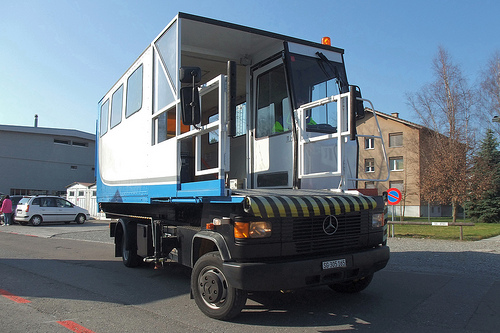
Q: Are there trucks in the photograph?
A: Yes, there is a truck.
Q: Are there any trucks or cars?
A: Yes, there is a truck.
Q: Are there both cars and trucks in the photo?
A: Yes, there are both a truck and a car.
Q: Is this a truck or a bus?
A: This is a truck.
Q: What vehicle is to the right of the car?
A: The vehicle is a truck.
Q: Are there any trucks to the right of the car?
A: Yes, there is a truck to the right of the car.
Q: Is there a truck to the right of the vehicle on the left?
A: Yes, there is a truck to the right of the car.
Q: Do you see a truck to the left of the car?
A: No, the truck is to the right of the car.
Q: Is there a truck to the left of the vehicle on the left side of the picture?
A: No, the truck is to the right of the car.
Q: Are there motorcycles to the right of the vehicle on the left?
A: No, there is a truck to the right of the car.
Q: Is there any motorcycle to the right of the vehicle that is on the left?
A: No, there is a truck to the right of the car.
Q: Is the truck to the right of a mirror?
A: No, the truck is to the right of a car.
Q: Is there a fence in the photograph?
A: No, there are no fences.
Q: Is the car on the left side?
A: Yes, the car is on the left of the image.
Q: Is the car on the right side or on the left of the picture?
A: The car is on the left of the image.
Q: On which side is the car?
A: The car is on the left of the image.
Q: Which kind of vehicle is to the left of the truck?
A: The vehicle is a car.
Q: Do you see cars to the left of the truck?
A: Yes, there is a car to the left of the truck.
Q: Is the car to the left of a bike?
A: No, the car is to the left of a truck.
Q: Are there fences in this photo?
A: No, there are no fences.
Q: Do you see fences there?
A: No, there are no fences.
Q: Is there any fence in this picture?
A: No, there are no fences.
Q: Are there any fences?
A: No, there are no fences.